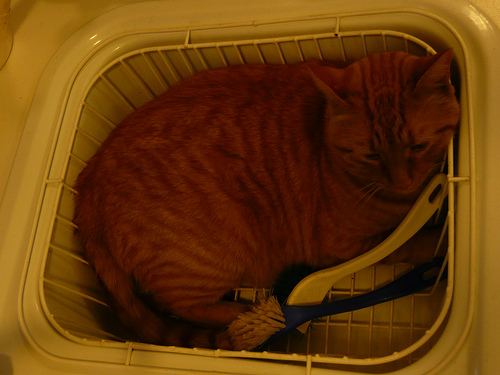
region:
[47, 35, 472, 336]
A cat laying down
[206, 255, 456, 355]
Blue scrub brush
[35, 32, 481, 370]
Cat in sink with brushes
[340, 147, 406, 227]
Cat whiskers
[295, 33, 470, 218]
Cat head with eyes and ears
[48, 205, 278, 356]
Cat's tail in sink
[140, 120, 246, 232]
Orange fur of a cat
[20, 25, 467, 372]
Cat laying in sink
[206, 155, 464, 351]
Two scrub brushes along side of cat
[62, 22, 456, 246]
Orange and brown cat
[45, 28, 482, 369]
cat curled up in a wire basket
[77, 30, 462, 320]
orange cat with darker stripes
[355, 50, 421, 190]
dark stripes down the center of cat's head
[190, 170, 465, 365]
black and white brushes in corner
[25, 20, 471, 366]
wire basket fitted into solid container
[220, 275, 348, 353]
white bristles on a darker base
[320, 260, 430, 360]
rectangular grids of wire basket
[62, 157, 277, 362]
cat's tail curled around rear of body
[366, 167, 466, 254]
oval opening on end of handle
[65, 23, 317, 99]
vertical and coated wires on side of basket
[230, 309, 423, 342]
Blue and white brush in basket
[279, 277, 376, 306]
Black and white brush in basket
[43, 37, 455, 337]
Orange cat in basket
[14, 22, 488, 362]
White wire basket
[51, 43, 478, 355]
Cat laying in basket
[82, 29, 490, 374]
Cat curled up in basket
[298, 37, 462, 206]
Cat looking forward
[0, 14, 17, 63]
Jar on a shelf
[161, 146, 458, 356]
Two brushes next to a cat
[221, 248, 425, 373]
Black and Blue brush together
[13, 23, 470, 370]
a cat sitting in a sink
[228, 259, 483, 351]
a white brush with a black handle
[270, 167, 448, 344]
a black brush with a white handle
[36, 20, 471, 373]
a metel basket in a sink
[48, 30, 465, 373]
a cat sitting in a metal basket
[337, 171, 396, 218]
the whiskers of a cat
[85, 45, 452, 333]
an orange cat with stripes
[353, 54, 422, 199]
vertical stripes on the head of the cat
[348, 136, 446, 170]
dark eyes of a cat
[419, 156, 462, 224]
a hole in the handle of a brush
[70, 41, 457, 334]
An orange cat with stripes.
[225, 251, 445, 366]
The dish brush has a blue handle.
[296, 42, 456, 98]
The cat has two ears.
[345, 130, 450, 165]
The cat has two eyes.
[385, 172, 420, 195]
The cat has a nose.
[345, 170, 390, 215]
The cat has whiskers.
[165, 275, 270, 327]
The hind leg of the cat.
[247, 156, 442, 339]
The brush has a white handle.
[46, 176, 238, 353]
The cat has a tail.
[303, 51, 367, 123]
The ear of the cat.